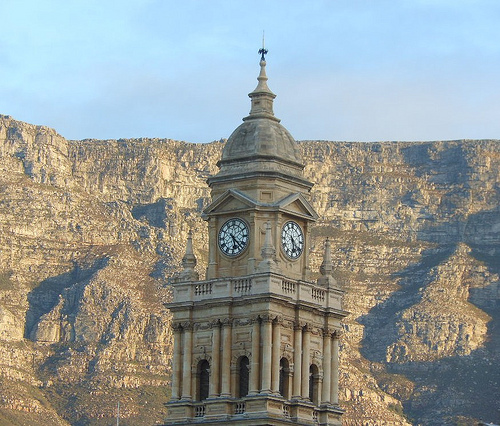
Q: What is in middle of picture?
A: Building with clock.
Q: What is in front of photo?
A: Building with two clocks.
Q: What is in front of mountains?
A: Building in sunlight.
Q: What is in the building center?
A: Two medium white clocks.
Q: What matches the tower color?
A: Mountain is brown.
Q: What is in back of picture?
A: Mountain behind the clock.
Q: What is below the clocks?
A: Windows attached to tower.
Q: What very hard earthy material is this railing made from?
A: Stone.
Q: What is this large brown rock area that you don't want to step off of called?
A: Cliff.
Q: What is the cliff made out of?
A: Rock.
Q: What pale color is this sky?
A: Blue.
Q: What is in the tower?
A: Clocks.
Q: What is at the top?
A: Steeple.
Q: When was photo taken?
A: Daytime.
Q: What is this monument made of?
A: Stone.